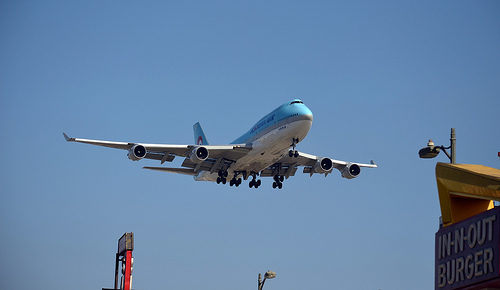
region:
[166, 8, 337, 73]
this is the sky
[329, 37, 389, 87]
the sky is blue in color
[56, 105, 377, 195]
this is an airplane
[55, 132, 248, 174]
this is the airplane's wing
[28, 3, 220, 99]
the sky is clear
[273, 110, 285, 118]
the airplane is blue in color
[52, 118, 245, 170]
the wing is big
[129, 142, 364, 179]
there are four propellers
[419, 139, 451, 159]
this is a street light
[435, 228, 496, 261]
this is a signboard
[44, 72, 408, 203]
large blue and silver jet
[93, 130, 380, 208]
large jet with four engines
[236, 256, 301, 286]
street light under a large jet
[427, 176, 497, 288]
fast food advertisement sign with the letter i on it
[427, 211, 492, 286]
fast food advertisement sign with the letter n on it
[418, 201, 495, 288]
fast food advertisement sign with the letter o on it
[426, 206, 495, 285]
fast food advertisement sign with the letter u on it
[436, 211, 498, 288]
fast food advertisement sign with the letter t on it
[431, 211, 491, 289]
fast food advertisement sign with the letter b on it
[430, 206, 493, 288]
fast food advertisement sign with the letter r on it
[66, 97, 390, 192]
this is a plane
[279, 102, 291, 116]
the plane is blue in color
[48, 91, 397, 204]
the plane is on air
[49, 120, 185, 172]
this is the right wing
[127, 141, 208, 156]
the propellers are two in number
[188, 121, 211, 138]
this is the tail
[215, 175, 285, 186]
these are the wheels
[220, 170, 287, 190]
the wheels are black in color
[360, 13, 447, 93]
the sky is clear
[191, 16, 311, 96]
the sky is blue in color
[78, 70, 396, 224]
a blue and white plane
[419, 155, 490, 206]
a yellow arrow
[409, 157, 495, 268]
a burger sign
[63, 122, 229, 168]
wing of the plan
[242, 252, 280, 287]
a street light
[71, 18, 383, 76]
clear skies today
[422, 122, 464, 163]
another street light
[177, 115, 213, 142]
tail of the plane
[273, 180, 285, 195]
wheel of the plane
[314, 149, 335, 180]
one of four engines of the plane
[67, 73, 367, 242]
blue and white plane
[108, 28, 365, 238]
plane in the air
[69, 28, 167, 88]
blue sky in background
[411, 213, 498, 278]
Burger place below plane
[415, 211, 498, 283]
sign that says "In-N-Out Burger"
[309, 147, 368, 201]
two engines on left side of plane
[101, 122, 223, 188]
two engines on right side of plane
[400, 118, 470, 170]
light above the street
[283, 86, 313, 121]
front window of plane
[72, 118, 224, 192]
right wing of plane